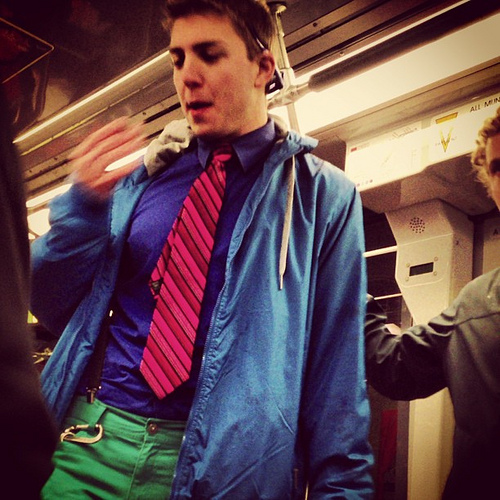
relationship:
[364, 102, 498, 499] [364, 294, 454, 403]
man has a arm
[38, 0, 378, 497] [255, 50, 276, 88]
man has an ear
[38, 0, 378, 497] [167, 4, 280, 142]
man has a head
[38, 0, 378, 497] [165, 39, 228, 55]
man has eyebrows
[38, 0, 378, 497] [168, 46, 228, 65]
man has eyes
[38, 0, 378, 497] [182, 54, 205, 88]
man has a nose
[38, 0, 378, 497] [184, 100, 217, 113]
man has a mouth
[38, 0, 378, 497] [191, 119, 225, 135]
man has a chin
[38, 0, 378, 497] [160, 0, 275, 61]
man has hair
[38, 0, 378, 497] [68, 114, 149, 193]
man has a hand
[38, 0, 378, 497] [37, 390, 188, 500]
man wearing pants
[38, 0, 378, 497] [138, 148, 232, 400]
man wearing a red tie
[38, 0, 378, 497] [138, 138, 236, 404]
man wearing a red tie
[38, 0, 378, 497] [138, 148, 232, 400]
man has a red tie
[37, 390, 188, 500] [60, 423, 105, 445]
pants have a clip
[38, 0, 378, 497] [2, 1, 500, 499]
man riding a subway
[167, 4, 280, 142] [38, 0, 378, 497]
head on top of a man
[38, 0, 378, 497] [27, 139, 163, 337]
man has an arm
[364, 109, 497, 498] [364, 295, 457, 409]
man has an arm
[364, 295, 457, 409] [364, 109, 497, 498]
arm attached to a man